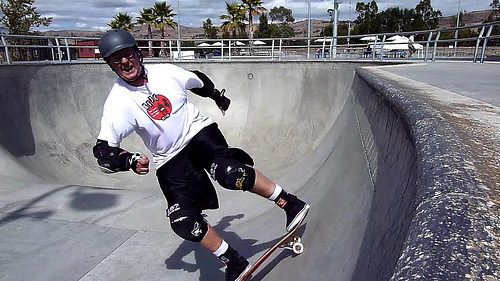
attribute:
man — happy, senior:
[92, 31, 307, 280]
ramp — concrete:
[242, 60, 490, 280]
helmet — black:
[98, 29, 138, 63]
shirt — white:
[95, 64, 220, 170]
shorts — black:
[157, 124, 253, 208]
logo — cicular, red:
[143, 94, 173, 122]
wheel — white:
[290, 241, 306, 254]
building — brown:
[77, 37, 100, 58]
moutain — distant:
[38, 9, 498, 45]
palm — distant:
[149, 1, 177, 38]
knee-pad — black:
[166, 205, 207, 241]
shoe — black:
[217, 244, 250, 281]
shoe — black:
[276, 187, 305, 227]